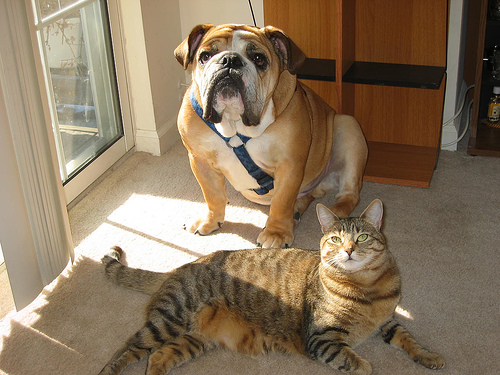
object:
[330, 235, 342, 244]
eye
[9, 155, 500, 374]
floor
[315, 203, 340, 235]
ear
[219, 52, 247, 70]
nose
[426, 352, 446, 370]
cat's paw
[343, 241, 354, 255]
nose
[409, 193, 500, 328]
carpet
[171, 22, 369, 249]
dog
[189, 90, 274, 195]
strap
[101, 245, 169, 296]
tail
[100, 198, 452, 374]
cat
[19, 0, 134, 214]
door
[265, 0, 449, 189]
shelf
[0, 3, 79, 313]
blinds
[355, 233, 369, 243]
eye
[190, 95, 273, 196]
harness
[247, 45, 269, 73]
eye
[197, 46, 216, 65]
eye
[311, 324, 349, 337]
stripe